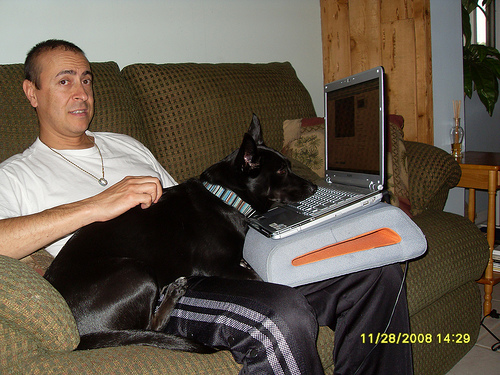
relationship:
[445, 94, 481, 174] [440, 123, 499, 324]
item on table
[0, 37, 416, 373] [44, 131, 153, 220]
man wears necklace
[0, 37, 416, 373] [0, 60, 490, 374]
man on couch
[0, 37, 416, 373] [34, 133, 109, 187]
man with necklace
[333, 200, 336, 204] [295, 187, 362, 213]
key near keyboard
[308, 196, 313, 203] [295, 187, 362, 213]
key near keyboard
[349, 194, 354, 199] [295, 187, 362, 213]
key near keyboard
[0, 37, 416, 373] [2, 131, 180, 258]
man in t-shirt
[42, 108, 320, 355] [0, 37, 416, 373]
dog on man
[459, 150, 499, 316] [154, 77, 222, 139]
table standing next to couch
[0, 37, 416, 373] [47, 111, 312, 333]
man with dog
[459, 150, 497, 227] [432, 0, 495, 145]
table against wall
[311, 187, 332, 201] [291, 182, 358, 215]
key on keyboard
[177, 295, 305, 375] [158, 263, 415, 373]
stripes on pants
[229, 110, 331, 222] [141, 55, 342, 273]
head of a dog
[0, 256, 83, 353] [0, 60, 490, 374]
pillow on couch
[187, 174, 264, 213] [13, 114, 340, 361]
collar on dog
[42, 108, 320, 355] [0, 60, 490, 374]
dog on couch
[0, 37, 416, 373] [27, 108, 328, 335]
man next dog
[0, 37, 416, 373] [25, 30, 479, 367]
man sitting on couch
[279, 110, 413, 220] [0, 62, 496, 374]
pillow on couch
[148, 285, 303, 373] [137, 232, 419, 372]
stripes on pants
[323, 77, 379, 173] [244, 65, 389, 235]
screen of laptop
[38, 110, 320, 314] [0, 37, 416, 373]
dog of man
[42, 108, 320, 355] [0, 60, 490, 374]
dog of couch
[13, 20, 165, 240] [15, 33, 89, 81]
man with hair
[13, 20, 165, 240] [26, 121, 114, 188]
man with necklace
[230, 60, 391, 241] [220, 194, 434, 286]
laptop on a stand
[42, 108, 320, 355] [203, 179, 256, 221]
dog has collar